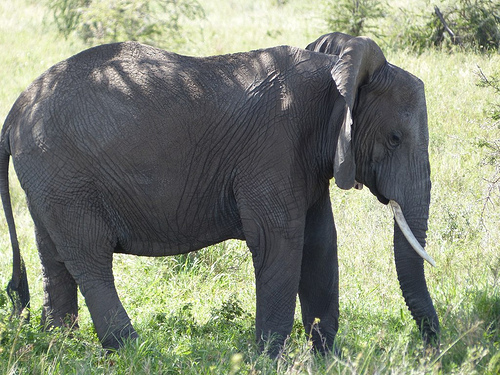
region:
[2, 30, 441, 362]
an elephant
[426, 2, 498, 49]
the base of a tree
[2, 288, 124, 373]
a clump of grass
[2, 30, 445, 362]
a grey elephant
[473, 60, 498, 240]
branches from a tree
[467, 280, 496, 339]
a green clump of grass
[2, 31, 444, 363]
a standing elephant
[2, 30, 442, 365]
an elephant with a white ivory tusk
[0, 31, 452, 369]
an elephant with saggy flesh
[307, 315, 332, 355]
a yellow flower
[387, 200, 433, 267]
the elephant's tusk on the right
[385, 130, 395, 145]
the elephant's right eye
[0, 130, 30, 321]
the elephant's tail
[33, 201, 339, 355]
the elephant's four legs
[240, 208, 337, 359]
the elephant's two front legs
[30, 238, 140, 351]
the elephant's two back legs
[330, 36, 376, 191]
the elephant's right ear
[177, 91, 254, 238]
an area of large wrinkles on the elephant's body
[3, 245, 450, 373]
the tall green grass under the elephant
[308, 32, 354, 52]
the top of the elephant's left ear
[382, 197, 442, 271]
white tusk on an elephant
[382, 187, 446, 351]
gray trunk of an elephant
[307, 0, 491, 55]
green foliage behind an elephant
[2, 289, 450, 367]
grass growing around the elephant's feet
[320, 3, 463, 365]
gray head of an elephant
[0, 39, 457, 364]
a gray elephant standing in the grass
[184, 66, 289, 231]
wrinkled gray skin of an elephant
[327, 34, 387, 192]
right gray ear of an elephant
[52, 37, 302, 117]
sun and shadows on an elephant's back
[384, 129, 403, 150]
right eye of an elephant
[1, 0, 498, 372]
an African elephant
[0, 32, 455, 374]
an elephant with tough grey skin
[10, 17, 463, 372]
an elephant with rough skin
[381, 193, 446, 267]
an elephant's long white tusk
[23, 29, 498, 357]
an elephant with its trunk in towards the ground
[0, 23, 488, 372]
an elephant walking through the grass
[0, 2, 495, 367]
an elephant alone in the field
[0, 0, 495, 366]
a big elephant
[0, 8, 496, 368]
a grey elephant walking in a field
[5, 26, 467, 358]
an elephant with a long trunk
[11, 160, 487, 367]
picture taken outdoors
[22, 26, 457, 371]
picture taken during the day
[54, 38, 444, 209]
shadows on the elephant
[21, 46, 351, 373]
a lone elephant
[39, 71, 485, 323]
the elephant is standing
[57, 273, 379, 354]
the elephant is on grass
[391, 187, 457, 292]
the elephant has a white tusk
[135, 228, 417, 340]
the grass is light green in color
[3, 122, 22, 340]
the elephant's tail is down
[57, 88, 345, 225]
the elephant has many wrinkles